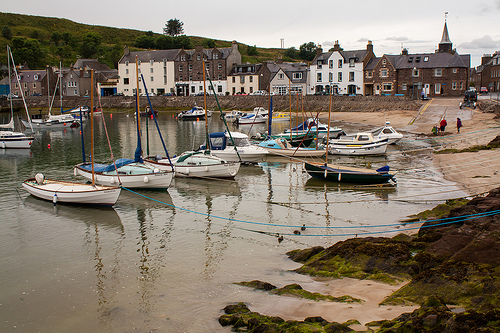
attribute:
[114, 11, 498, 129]
buildings — multiple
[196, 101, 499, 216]
shoreline — sandy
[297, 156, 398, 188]
boat — black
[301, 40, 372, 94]
building — white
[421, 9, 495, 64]
steeple — tall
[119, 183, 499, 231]
rope — blue